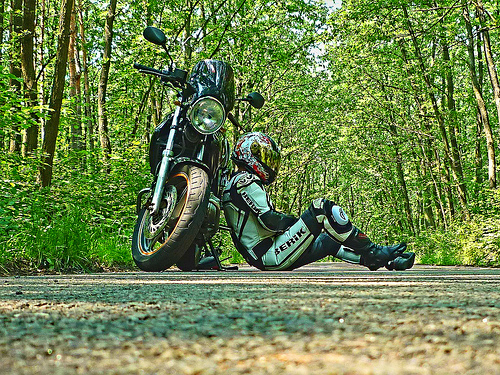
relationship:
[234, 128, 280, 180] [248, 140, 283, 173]
helmet has lens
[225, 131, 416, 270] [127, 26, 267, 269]
motor bike driver leaning against motor bike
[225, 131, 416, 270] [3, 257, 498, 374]
motor bike driver sitting on road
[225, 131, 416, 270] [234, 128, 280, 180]
motor bike driver wearing helmet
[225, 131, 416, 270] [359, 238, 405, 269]
motor bike driver wearing boot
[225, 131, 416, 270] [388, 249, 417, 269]
motor bike driver wearing boot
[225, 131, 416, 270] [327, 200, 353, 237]
motor bike driver wearing knee pad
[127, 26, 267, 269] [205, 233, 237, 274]
motor bike standing with kick stand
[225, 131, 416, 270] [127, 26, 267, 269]
motor bike driver sitting near motor bike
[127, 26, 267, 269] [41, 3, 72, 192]
motor bike parked near tree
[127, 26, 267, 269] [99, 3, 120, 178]
motor bike parked near tree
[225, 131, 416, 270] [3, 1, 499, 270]
motor bike driver sitting in forest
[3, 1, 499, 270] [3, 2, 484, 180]
forest almost covers sky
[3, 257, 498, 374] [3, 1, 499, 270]
road inside forest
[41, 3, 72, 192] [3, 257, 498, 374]
tree grown on side of road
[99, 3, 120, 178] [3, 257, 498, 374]
tree grown on side of road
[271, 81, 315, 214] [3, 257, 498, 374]
tree grown on side of road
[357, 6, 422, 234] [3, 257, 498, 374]
tree grown on side of road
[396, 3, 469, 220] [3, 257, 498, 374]
tree grown on side of road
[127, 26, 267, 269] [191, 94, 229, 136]
motor bike has headlight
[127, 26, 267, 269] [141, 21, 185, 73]
motor bike has rear view mirror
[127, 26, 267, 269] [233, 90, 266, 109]
motor bike has right mirror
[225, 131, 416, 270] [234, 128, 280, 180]
motor bike driver has helmet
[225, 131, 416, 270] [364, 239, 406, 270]
motor bike driver has right foot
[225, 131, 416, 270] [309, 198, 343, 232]
motor bike driver has right knee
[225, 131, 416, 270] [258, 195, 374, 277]
motor bike driver has pants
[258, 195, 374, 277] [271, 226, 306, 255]
pants have logo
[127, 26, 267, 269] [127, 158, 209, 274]
motor bike has front wheel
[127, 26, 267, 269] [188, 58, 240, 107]
motor bike has windshield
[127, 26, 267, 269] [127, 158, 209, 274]
motor bike has tire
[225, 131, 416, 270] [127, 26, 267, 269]
motor bike driver sitting by motor bike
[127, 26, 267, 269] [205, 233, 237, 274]
motor bike has kick stand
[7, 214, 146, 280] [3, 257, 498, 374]
grass on side of road